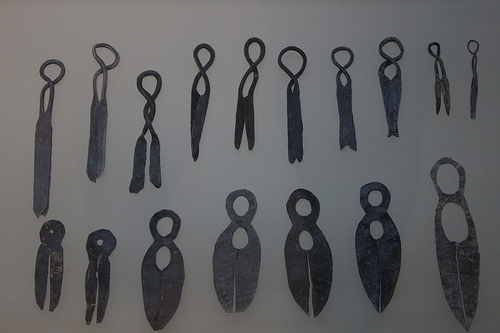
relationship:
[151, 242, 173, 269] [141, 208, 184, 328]
chest of stick person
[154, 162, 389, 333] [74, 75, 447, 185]
image of ties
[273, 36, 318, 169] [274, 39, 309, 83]
antique tool with loop